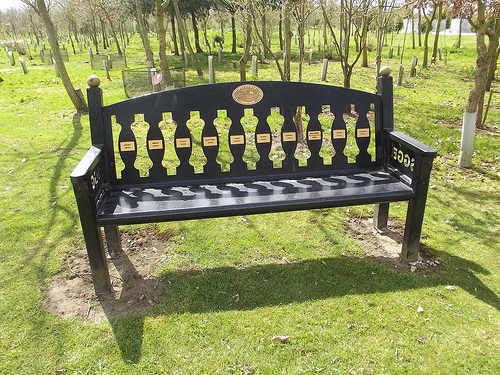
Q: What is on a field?
A: A bench.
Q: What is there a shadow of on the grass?
A: A bench.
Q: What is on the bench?
A: Small plaques.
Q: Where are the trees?
A: Behind the bench.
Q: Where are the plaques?
A: On the bench.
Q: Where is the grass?
A: On the ground.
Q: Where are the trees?
A: In the distance.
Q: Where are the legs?
A: On the bottom of the bench.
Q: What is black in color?
A: The bench.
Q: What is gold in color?
A: The plaques on the bench.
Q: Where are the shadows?
A: Underneath the bench.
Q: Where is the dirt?
A: Under the bench legs.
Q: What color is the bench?
A: Black.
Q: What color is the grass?
A: Green.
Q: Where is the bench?
A: On the grass.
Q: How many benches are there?
A: One.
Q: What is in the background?
A: Trees.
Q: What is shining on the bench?
A: The sun.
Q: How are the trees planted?
A: In rows.